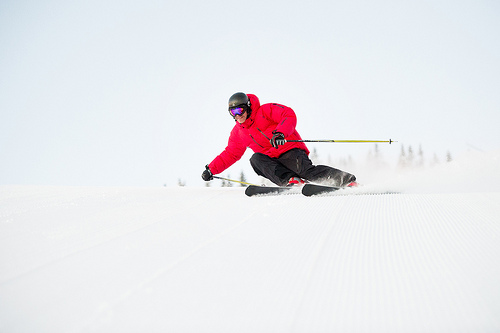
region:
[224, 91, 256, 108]
man has black helmet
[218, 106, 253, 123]
man has blue goggles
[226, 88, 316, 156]
red and black coat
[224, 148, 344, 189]
man has black pants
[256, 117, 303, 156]
man has black gloves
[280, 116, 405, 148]
black and yellow poles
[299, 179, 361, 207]
red and black skis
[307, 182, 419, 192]
skis kicking up snow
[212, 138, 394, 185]
two black and yellow ski poles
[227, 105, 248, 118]
black frame protective goggles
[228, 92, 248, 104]
the top of a helmet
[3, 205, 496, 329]
snow covering the mountain slope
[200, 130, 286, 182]
a pair of winter gloves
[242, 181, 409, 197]
a pair of black skis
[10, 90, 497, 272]
a man skiing on the snow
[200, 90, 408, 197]
a skier wearing ski gear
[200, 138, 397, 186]
two ski poles in the skier's hands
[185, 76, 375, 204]
skier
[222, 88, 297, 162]
red jacket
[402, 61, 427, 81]
white clouds in blue sky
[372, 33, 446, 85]
white clouds in blue sky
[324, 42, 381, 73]
white clouds in blue sky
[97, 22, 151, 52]
white clouds in blue sky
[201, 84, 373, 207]
A person snow skiing.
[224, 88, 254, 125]
A black safety helmet.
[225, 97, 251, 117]
A pair of ski goggles.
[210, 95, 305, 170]
A red winter jacket.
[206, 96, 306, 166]
A long sleeve jacket.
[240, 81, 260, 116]
A hood on the jacket.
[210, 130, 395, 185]
Skier with a pair of ski poles in both hands.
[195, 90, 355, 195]
Skier wearing a pair of skis.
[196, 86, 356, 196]
Skier wearing a pair of black gloves.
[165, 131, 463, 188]
A row of trees in the background.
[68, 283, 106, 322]
White snow covering the ground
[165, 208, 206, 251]
White snow covering the ground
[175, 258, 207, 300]
White snow covering the ground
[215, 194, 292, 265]
White snow covering the ground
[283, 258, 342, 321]
White snow covering the ground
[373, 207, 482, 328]
White snow covering the ground